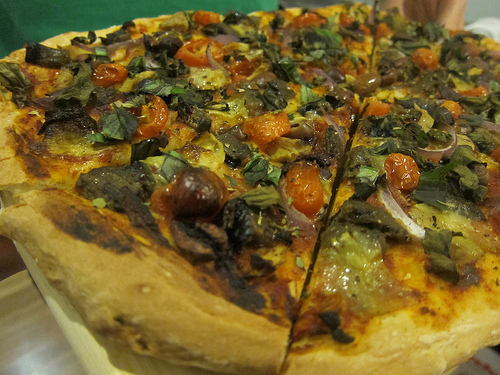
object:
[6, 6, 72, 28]
cross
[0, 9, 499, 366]
pizza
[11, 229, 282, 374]
tray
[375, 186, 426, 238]
onions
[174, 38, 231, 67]
tomatoes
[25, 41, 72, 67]
meat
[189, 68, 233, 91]
sauce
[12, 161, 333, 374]
crust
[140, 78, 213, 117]
kale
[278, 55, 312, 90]
peppers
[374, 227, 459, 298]
cheese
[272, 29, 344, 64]
toppings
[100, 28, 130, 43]
mushroom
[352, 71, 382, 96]
olive